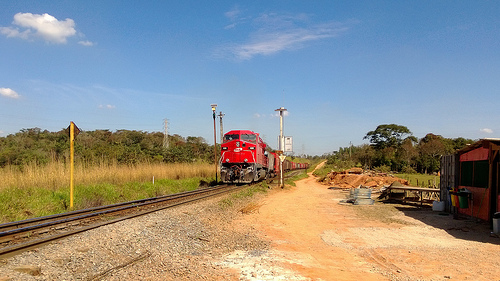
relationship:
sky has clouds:
[1, 0, 497, 159] [11, 13, 78, 49]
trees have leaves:
[363, 124, 468, 175] [387, 151, 395, 158]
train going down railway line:
[220, 129, 305, 180] [0, 181, 237, 256]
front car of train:
[219, 126, 264, 183] [220, 129, 305, 180]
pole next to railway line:
[69, 120, 78, 210] [0, 181, 237, 256]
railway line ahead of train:
[0, 181, 237, 256] [220, 129, 305, 180]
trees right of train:
[363, 124, 468, 175] [220, 129, 305, 180]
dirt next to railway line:
[234, 172, 495, 280] [0, 181, 237, 256]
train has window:
[220, 129, 305, 180] [242, 134, 254, 140]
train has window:
[220, 129, 305, 180] [226, 135, 236, 140]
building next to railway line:
[451, 141, 498, 218] [0, 181, 237, 256]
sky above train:
[1, 0, 497, 159] [220, 129, 305, 180]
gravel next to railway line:
[17, 203, 262, 280] [0, 181, 237, 256]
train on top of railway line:
[220, 129, 305, 180] [0, 181, 237, 256]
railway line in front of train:
[0, 181, 237, 256] [220, 129, 305, 180]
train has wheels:
[220, 129, 305, 180] [223, 166, 255, 181]